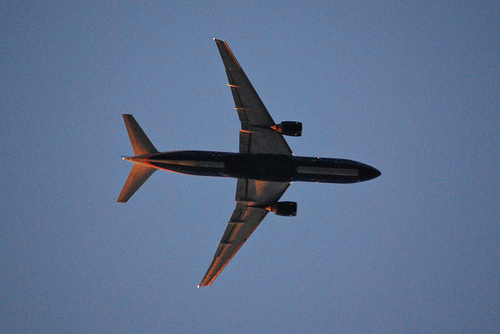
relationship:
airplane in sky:
[115, 36, 382, 290] [3, 2, 497, 334]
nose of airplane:
[356, 159, 383, 187] [115, 36, 382, 290]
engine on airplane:
[272, 119, 303, 138] [115, 36, 382, 290]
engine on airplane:
[264, 199, 297, 214] [115, 36, 382, 290]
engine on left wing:
[264, 199, 297, 214] [194, 176, 291, 290]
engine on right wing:
[272, 119, 303, 138] [211, 36, 304, 154]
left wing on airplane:
[194, 176, 291, 290] [115, 36, 382, 290]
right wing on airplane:
[211, 36, 304, 154] [115, 36, 382, 290]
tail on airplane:
[117, 112, 165, 206] [115, 36, 382, 290]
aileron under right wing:
[226, 83, 239, 88] [211, 36, 304, 154]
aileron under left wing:
[217, 241, 240, 246] [194, 176, 291, 290]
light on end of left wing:
[196, 283, 203, 291] [194, 176, 291, 290]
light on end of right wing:
[209, 36, 218, 41] [211, 36, 304, 154]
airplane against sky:
[115, 36, 382, 290] [3, 2, 497, 334]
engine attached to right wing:
[272, 119, 303, 138] [211, 36, 304, 154]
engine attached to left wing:
[264, 199, 297, 214] [194, 176, 291, 290]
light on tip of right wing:
[209, 36, 218, 41] [211, 36, 304, 154]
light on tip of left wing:
[196, 283, 203, 291] [194, 176, 291, 290]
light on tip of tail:
[119, 156, 128, 160] [117, 112, 165, 206]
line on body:
[139, 157, 361, 178] [146, 148, 360, 186]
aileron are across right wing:
[226, 83, 239, 88] [211, 36, 304, 154]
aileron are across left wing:
[217, 241, 240, 246] [194, 176, 291, 290]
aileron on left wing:
[208, 211, 240, 255] [194, 176, 291, 290]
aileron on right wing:
[224, 73, 245, 123] [211, 36, 304, 154]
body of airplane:
[146, 148, 360, 186] [115, 36, 382, 290]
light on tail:
[119, 156, 128, 160] [117, 112, 165, 206]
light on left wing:
[196, 283, 203, 291] [194, 176, 291, 290]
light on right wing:
[209, 36, 218, 41] [211, 36, 304, 154]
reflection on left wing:
[200, 238, 244, 289] [194, 176, 291, 290]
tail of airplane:
[117, 112, 165, 206] [115, 36, 382, 290]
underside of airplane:
[126, 46, 376, 280] [115, 36, 382, 290]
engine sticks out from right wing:
[272, 119, 303, 138] [211, 36, 304, 154]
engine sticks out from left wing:
[264, 199, 297, 214] [194, 176, 291, 290]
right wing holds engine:
[211, 36, 304, 154] [272, 119, 303, 138]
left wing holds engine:
[194, 176, 291, 290] [264, 199, 297, 214]